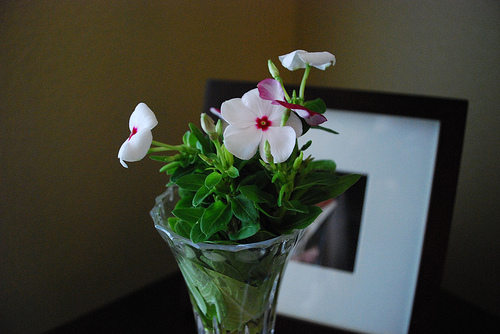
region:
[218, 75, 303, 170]
flower in glass vase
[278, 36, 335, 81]
flower in glass vase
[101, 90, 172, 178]
flower in glass vase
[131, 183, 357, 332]
glass vase for flowers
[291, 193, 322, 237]
green leaf of plant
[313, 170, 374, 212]
green leaf of plant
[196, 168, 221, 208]
green leaf of plant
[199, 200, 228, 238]
green leaf of plant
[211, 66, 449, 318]
framed picture in background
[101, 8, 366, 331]
flowers and leaves in vase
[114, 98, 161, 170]
White and purple flower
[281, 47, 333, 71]
White flower facing up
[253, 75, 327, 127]
Dark purple flower facing up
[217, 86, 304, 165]
White and purple flower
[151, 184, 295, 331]
Clear vase with alot of green in it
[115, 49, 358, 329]
Beautiful and vibrant leaves and flowers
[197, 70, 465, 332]
White and black picture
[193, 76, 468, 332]
Jet black picture frame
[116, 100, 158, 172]
White flower facing west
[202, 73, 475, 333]
Black and white square object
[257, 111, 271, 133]
hot pink center in a white bloom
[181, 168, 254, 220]
small dark green plant leaves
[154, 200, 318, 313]
a clear glass vase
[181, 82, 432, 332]
a picture frame behind the vase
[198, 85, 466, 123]
a black picture frame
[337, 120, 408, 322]
white inset in frame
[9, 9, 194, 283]
a plain gray wall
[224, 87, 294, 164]
a white flower with pink stamen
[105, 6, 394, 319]
a vase of freshly picked flowers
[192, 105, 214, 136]
a green bud on the stem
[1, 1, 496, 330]
corner of dark room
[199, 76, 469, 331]
picture in square frame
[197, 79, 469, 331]
black frame around white mat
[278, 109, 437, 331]
white mat around picture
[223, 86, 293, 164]
white petals on leaves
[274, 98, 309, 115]
red petal on flower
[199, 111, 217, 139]
closed bud of flower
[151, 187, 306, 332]
glass vase with uneven edge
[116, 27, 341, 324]
some flowers in a vase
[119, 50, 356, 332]
white flowers in a vase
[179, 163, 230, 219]
the leaves of a flowering plant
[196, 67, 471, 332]
a picture in a black frame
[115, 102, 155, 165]
a white flower with a red center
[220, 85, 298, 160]
a white flower with a red center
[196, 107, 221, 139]
a white bud of a flower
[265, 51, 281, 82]
a white bud of a flower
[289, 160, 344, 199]
the leaves of a plant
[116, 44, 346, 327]
a clear glass vase with flowers in it